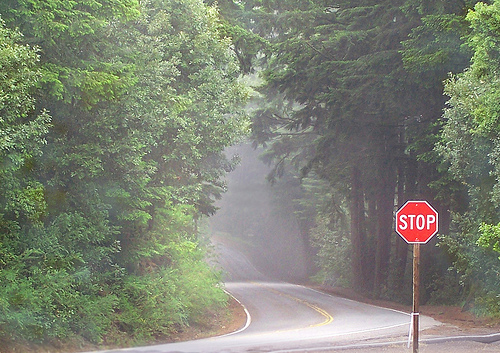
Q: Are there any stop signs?
A: Yes, there is a stop sign.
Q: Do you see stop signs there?
A: Yes, there is a stop sign.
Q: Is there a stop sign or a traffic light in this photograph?
A: Yes, there is a stop sign.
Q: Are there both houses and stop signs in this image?
A: No, there is a stop sign but no houses.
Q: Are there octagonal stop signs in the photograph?
A: Yes, there is an octagonal stop sign.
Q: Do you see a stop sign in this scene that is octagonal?
A: Yes, there is a stop sign that is octagonal.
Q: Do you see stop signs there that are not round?
A: Yes, there is a octagonal stop sign.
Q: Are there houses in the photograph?
A: No, there are no houses.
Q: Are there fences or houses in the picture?
A: No, there are no houses or fences.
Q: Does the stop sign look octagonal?
A: Yes, the stop sign is octagonal.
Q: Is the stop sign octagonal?
A: Yes, the stop sign is octagonal.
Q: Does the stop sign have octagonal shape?
A: Yes, the stop sign is octagonal.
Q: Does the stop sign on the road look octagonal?
A: Yes, the stop sign is octagonal.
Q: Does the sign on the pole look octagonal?
A: Yes, the stop sign is octagonal.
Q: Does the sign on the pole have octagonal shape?
A: Yes, the stop sign is octagonal.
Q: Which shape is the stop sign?
A: The stop sign is octagonal.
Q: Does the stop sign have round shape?
A: No, the stop sign is octagonal.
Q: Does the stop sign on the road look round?
A: No, the stop sign is octagonal.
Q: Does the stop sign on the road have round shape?
A: No, the stop sign is octagonal.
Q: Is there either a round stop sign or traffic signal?
A: No, there is a stop sign but it is octagonal.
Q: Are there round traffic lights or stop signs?
A: No, there is a stop sign but it is octagonal.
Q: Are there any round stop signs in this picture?
A: No, there is a stop sign but it is octagonal.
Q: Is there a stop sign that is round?
A: No, there is a stop sign but it is octagonal.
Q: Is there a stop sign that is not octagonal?
A: No, there is a stop sign but it is octagonal.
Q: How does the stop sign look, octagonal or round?
A: The stop sign is octagonal.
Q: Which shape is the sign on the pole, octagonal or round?
A: The stop sign is octagonal.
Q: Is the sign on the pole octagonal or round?
A: The stop sign is octagonal.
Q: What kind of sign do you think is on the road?
A: The sign is a stop sign.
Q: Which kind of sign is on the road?
A: The sign is a stop sign.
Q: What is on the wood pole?
A: The stop sign is on the pole.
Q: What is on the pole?
A: The stop sign is on the pole.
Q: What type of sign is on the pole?
A: The sign is a stop sign.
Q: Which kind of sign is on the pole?
A: The sign is a stop sign.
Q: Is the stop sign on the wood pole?
A: Yes, the stop sign is on the pole.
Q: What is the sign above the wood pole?
A: The sign is a stop sign.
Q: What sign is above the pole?
A: The sign is a stop sign.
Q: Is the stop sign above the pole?
A: Yes, the stop sign is above the pole.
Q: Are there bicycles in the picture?
A: No, there are no bicycles.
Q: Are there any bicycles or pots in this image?
A: No, there are no bicycles or pots.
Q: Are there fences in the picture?
A: No, there are no fences.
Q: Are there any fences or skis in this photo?
A: No, there are no fences or skis.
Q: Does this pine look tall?
A: Yes, the pine is tall.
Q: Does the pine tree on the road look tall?
A: Yes, the pine tree is tall.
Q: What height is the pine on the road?
A: The pine is tall.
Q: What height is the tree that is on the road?
A: The pine is tall.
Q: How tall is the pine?
A: The pine is tall.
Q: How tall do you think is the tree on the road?
A: The pine is tall.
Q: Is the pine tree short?
A: No, the pine tree is tall.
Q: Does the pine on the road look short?
A: No, the pine is tall.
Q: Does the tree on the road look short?
A: No, the pine is tall.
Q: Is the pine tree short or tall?
A: The pine tree is tall.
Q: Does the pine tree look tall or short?
A: The pine tree is tall.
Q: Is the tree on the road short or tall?
A: The pine tree is tall.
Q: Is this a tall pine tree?
A: Yes, this is a tall pine tree.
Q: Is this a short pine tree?
A: No, this is a tall pine tree.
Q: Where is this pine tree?
A: The pine tree is on the road.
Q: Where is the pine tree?
A: The pine tree is on the road.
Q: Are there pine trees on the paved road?
A: Yes, there is a pine tree on the road.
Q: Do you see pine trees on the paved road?
A: Yes, there is a pine tree on the road.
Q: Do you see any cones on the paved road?
A: No, there is a pine tree on the road.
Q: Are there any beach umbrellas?
A: No, there are no beach umbrellas.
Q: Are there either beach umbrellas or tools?
A: No, there are no beach umbrellas or tools.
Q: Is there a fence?
A: No, there are no fences.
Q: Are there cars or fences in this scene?
A: No, there are no fences or cars.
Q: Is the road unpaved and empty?
A: No, the road is empty but paved.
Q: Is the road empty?
A: Yes, the road is empty.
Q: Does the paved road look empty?
A: Yes, the road is empty.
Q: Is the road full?
A: No, the road is empty.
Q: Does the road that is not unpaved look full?
A: No, the road is empty.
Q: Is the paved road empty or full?
A: The road is empty.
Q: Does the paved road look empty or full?
A: The road is empty.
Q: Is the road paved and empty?
A: Yes, the road is paved and empty.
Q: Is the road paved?
A: Yes, the road is paved.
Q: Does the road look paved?
A: Yes, the road is paved.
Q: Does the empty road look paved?
A: Yes, the road is paved.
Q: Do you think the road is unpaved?
A: No, the road is paved.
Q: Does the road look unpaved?
A: No, the road is paved.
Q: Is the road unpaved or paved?
A: The road is paved.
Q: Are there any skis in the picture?
A: No, there are no skis.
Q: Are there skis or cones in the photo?
A: No, there are no skis or cones.